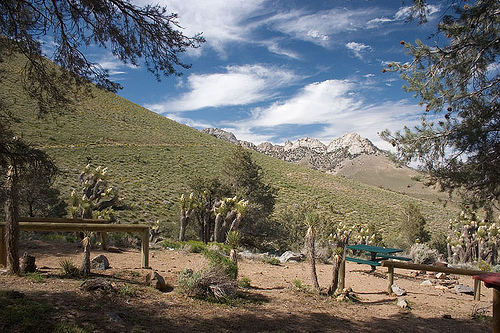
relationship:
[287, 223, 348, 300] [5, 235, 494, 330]
trunks on ground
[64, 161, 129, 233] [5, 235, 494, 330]
cactus in ground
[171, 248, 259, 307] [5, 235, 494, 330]
bush in ground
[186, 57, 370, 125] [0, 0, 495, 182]
clouds in sky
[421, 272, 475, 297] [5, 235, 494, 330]
rocks resting on ground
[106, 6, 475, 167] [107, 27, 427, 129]
clouds in sky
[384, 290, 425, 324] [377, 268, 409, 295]
rock stacked on rock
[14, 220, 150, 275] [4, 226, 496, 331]
wooden post in dirt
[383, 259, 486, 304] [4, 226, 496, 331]
wooden post in dirt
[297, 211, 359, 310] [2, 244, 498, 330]
cacti in dirt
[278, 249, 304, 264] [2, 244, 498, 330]
rock laying on dirt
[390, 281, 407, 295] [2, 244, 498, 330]
rock laying on dirt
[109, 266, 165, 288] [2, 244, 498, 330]
rock laying on dirt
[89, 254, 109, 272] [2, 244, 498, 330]
rock laying on dirt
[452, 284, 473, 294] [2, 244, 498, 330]
rock laying on dirt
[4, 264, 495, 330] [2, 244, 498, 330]
shadows cast on dirt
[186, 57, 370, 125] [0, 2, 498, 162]
clouds in sky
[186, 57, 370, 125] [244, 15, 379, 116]
clouds are in sky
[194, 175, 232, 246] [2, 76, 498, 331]
tree in desert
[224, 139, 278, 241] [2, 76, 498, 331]
tree in desert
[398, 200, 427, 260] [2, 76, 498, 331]
tree in desert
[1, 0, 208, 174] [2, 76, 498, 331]
tree in desert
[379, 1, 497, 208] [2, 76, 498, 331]
tree in desert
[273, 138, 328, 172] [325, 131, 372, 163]
mountain next to mountain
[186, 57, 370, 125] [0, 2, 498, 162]
clouds are in sky